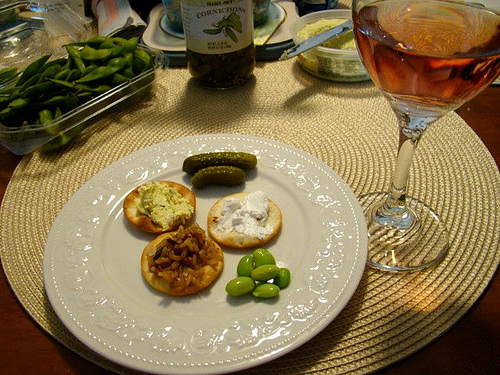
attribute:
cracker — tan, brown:
[206, 191, 288, 251]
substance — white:
[208, 183, 283, 245]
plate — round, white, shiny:
[21, 128, 334, 349]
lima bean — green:
[223, 274, 256, 301]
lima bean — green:
[252, 280, 277, 301]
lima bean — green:
[279, 263, 287, 288]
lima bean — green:
[253, 264, 271, 283]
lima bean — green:
[238, 253, 259, 285]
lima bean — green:
[249, 252, 272, 271]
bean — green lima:
[253, 280, 278, 301]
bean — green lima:
[223, 275, 253, 296]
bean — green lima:
[247, 261, 277, 281]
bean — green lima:
[252, 245, 274, 268]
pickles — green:
[180, 150, 258, 186]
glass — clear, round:
[356, 0, 478, 370]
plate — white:
[26, 115, 384, 350]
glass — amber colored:
[347, 52, 458, 309]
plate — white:
[96, 98, 413, 355]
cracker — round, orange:
[139, 231, 219, 292]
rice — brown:
[158, 234, 203, 286]